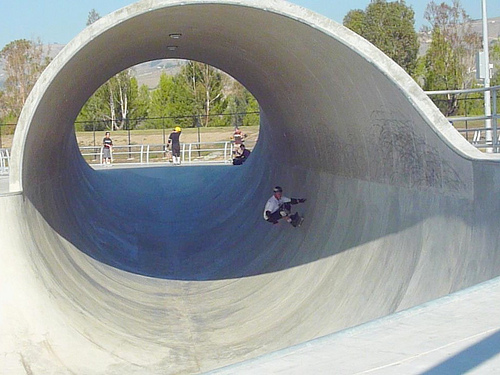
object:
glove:
[299, 198, 306, 202]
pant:
[267, 207, 290, 223]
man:
[164, 126, 184, 165]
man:
[103, 131, 113, 167]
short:
[104, 149, 111, 158]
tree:
[340, 0, 416, 75]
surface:
[192, 278, 500, 374]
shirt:
[263, 195, 291, 221]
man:
[263, 186, 308, 228]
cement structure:
[0, 0, 500, 375]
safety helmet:
[273, 186, 282, 192]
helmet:
[274, 187, 283, 192]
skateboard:
[290, 213, 299, 227]